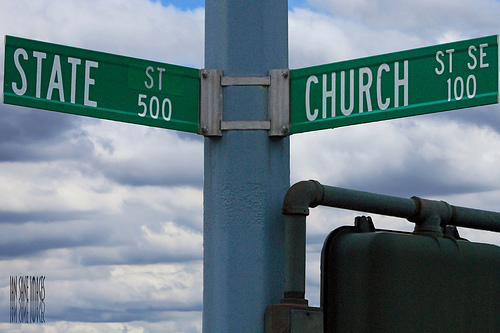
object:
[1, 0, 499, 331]
sky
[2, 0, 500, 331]
clouds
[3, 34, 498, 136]
sigs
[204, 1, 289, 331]
pole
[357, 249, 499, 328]
umbers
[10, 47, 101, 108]
words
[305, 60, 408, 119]
letters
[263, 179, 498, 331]
poles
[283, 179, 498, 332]
pipe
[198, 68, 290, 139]
bolts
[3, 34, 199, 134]
sign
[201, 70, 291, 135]
metal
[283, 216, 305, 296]
rod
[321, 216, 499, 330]
box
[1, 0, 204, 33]
light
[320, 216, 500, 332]
back